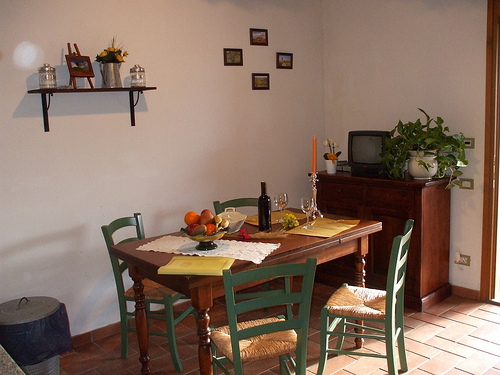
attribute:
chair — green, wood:
[213, 262, 337, 367]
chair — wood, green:
[336, 228, 425, 362]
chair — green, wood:
[206, 192, 261, 225]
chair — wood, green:
[84, 211, 165, 372]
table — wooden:
[135, 210, 405, 325]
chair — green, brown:
[325, 221, 442, 371]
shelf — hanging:
[27, 77, 184, 142]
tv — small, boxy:
[336, 118, 405, 182]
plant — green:
[390, 126, 460, 145]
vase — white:
[401, 150, 441, 199]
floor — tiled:
[407, 300, 488, 372]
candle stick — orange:
[309, 133, 317, 173]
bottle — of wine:
[260, 179, 270, 228]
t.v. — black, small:
[349, 129, 396, 172]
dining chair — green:
[316, 216, 415, 373]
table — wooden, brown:
[109, 205, 382, 373]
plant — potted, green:
[379, 107, 469, 191]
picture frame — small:
[253, 73, 269, 90]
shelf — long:
[24, 87, 157, 96]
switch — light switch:
[459, 179, 476, 190]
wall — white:
[320, 0, 487, 297]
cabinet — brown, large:
[309, 165, 458, 305]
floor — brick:
[64, 294, 498, 373]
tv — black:
[348, 130, 393, 171]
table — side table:
[308, 160, 457, 308]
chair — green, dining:
[208, 256, 320, 373]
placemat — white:
[139, 231, 279, 267]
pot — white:
[407, 143, 441, 181]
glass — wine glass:
[300, 198, 313, 230]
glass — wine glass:
[272, 189, 289, 230]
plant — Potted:
[389, 107, 469, 187]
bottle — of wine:
[259, 183, 272, 233]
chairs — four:
[100, 171, 427, 364]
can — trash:
[10, 281, 72, 368]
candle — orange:
[298, 130, 324, 180]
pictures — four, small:
[221, 22, 308, 98]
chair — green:
[324, 220, 416, 370]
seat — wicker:
[328, 278, 388, 319]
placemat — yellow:
[287, 215, 363, 245]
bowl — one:
[185, 207, 247, 239]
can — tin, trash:
[0, 286, 75, 373]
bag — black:
[5, 314, 63, 356]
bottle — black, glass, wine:
[253, 182, 272, 233]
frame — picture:
[250, 17, 271, 46]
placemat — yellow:
[160, 253, 244, 288]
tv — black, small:
[339, 115, 409, 179]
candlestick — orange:
[306, 130, 329, 180]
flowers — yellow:
[101, 44, 124, 63]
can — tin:
[95, 60, 125, 90]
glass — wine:
[292, 189, 329, 240]